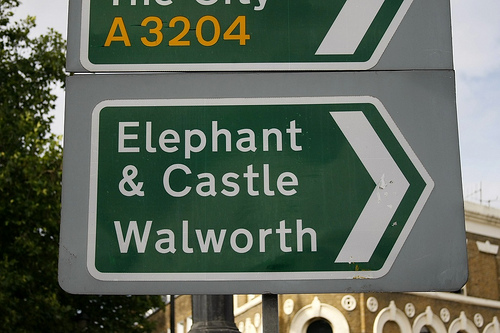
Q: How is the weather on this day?
A: It is cloudy.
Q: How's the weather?
A: It is cloudy.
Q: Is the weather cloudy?
A: Yes, it is cloudy.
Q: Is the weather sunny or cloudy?
A: It is cloudy.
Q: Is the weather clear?
A: No, it is cloudy.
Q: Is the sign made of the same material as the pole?
A: Yes, both the sign and the pole are made of metal.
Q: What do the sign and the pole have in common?
A: The material, both the sign and the pole are metallic.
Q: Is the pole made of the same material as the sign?
A: Yes, both the pole and the sign are made of metal.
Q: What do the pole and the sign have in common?
A: The material, both the pole and the sign are metallic.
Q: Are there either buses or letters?
A: Yes, there are letters.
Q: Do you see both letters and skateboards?
A: No, there are letters but no skateboards.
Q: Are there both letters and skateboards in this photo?
A: No, there are letters but no skateboards.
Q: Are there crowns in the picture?
A: No, there are no crowns.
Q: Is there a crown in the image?
A: No, there are no crowns.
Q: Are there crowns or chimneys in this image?
A: No, there are no crowns or chimneys.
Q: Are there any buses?
A: No, there are no buses.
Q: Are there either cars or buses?
A: No, there are no buses or cars.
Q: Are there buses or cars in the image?
A: No, there are no buses or cars.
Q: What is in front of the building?
A: The sign is in front of the building.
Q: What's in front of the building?
A: The sign is in front of the building.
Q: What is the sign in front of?
A: The sign is in front of the building.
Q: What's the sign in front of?
A: The sign is in front of the building.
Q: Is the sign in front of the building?
A: Yes, the sign is in front of the building.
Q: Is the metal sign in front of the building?
A: Yes, the sign is in front of the building.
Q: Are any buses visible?
A: No, there are no buses.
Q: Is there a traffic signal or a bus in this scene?
A: No, there are no buses or traffic lights.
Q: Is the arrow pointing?
A: Yes, the arrow is pointing.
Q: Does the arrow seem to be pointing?
A: Yes, the arrow is pointing.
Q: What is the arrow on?
A: The arrow is on the sign.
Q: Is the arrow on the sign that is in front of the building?
A: Yes, the arrow is on the sign.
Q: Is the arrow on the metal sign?
A: Yes, the arrow is on the sign.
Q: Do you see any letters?
A: Yes, there are letters.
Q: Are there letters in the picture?
A: Yes, there are letters.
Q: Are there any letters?
A: Yes, there are letters.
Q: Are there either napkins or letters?
A: Yes, there are letters.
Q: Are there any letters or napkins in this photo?
A: Yes, there are letters.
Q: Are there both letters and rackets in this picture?
A: No, there are letters but no rackets.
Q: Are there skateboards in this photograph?
A: No, there are no skateboards.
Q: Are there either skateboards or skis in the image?
A: No, there are no skateboards or skis.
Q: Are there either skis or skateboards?
A: No, there are no skateboards or skis.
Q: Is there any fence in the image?
A: No, there are no fences.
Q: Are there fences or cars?
A: No, there are no fences or cars.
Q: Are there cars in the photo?
A: No, there are no cars.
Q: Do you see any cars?
A: No, there are no cars.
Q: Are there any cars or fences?
A: No, there are no cars or fences.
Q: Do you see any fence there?
A: No, there are no fences.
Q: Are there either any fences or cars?
A: No, there are no fences or cars.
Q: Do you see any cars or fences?
A: No, there are no fences or cars.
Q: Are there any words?
A: Yes, there are words.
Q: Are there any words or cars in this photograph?
A: Yes, there are words.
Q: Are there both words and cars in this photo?
A: No, there are words but no cars.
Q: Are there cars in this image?
A: No, there are no cars.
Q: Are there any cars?
A: No, there are no cars.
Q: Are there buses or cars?
A: No, there are no cars or buses.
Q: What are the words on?
A: The words are on the sign.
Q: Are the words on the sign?
A: Yes, the words are on the sign.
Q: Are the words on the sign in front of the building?
A: Yes, the words are on the sign.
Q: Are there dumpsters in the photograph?
A: No, there are no dumpsters.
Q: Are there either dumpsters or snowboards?
A: No, there are no dumpsters or snowboards.